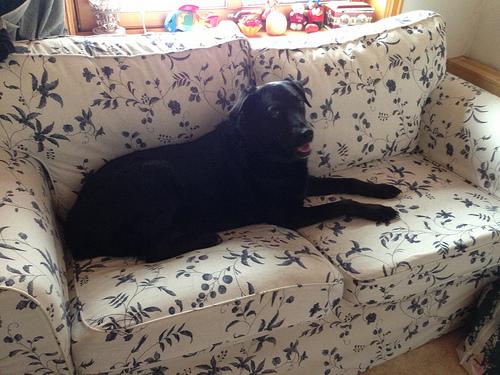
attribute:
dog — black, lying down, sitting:
[58, 82, 405, 268]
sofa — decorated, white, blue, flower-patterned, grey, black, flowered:
[3, 0, 498, 373]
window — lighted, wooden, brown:
[65, 2, 403, 29]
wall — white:
[404, 0, 500, 83]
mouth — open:
[292, 135, 314, 161]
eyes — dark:
[268, 98, 309, 122]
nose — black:
[293, 125, 314, 143]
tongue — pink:
[300, 144, 311, 154]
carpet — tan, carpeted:
[375, 326, 471, 374]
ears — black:
[232, 85, 308, 126]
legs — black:
[296, 175, 404, 221]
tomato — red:
[307, 25, 320, 33]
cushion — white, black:
[252, 11, 441, 157]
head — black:
[240, 89, 315, 165]